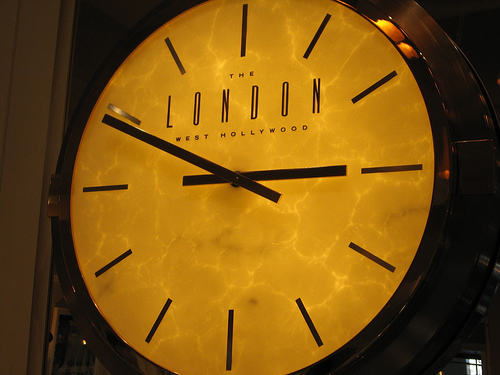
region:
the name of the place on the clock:
[150, 68, 326, 142]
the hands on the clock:
[100, 109, 349, 201]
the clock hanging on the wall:
[56, 5, 451, 367]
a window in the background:
[461, 347, 483, 373]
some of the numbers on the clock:
[341, 78, 421, 278]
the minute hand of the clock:
[178, 151, 343, 185]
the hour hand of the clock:
[95, 103, 282, 203]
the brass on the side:
[42, 183, 62, 220]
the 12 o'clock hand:
[233, 3, 250, 57]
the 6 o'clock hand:
[217, 306, 237, 373]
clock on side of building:
[57, 10, 459, 355]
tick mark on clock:
[211, 307, 247, 371]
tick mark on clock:
[283, 296, 321, 360]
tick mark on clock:
[336, 223, 395, 283]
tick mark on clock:
[151, 289, 193, 341]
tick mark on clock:
[92, 243, 154, 291]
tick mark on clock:
[82, 176, 145, 211]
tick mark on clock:
[354, 153, 427, 189]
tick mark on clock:
[150, 30, 203, 90]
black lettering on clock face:
[144, 58, 341, 150]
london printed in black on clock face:
[156, 79, 339, 130]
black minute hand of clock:
[101, 111, 281, 206]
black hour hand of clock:
[171, 155, 344, 193]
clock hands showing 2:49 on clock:
[86, 78, 436, 244]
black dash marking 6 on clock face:
[215, 305, 247, 373]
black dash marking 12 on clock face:
[236, 6, 251, 53]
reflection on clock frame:
[352, 6, 457, 184]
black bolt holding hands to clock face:
[224, 168, 244, 186]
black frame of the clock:
[49, 11, 475, 342]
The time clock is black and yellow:
[31, 17, 483, 372]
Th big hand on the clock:
[103, 111, 278, 206]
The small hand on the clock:
[176, 163, 356, 189]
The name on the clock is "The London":
[161, 70, 326, 147]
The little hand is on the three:
[175, 159, 426, 184]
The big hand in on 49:
[101, 108, 284, 208]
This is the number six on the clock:
[214, 301, 251, 371]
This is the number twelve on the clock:
[235, 0, 250, 62]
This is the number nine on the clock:
[80, 181, 132, 201]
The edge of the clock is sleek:
[357, 12, 499, 372]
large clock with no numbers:
[53, 1, 443, 373]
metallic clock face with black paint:
[65, 0, 444, 371]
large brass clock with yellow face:
[48, 1, 495, 373]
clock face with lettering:
[66, 0, 439, 374]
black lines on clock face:
[73, 0, 438, 372]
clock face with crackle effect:
[73, 0, 438, 373]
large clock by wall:
[5, 2, 438, 372]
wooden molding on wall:
[21, 8, 78, 373]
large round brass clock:
[43, 8, 483, 373]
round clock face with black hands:
[69, 0, 435, 374]